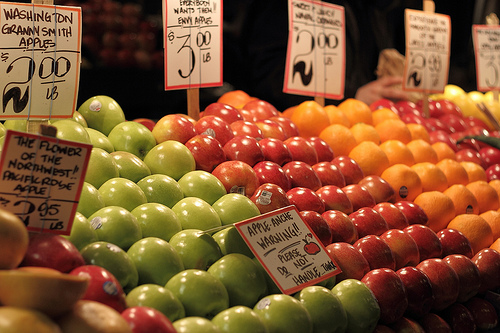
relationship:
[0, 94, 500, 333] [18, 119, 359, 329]
apple of apples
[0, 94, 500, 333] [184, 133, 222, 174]
apple of apple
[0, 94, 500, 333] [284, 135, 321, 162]
apple of apple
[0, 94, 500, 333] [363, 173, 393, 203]
apple of apple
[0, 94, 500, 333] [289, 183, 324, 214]
apple of apple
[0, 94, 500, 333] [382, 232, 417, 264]
apple of apple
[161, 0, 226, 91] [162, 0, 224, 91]
price sign label price sign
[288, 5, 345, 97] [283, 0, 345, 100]
sign says sign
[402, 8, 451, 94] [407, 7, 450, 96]
price has price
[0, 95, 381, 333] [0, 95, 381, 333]
apples in apples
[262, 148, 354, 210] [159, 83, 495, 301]
red apples in pile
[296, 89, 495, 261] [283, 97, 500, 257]
oranges in oranges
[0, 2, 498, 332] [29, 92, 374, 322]
stand back fruit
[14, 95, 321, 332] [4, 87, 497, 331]
apples on display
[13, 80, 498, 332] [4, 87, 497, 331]
apple on display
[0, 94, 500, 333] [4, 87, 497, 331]
apple on display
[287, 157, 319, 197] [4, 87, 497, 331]
red apple on display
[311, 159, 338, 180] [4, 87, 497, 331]
red apple on display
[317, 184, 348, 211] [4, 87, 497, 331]
red apple on display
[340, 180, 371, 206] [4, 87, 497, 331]
red apple on display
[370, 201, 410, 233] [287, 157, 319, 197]
red apple on red apple